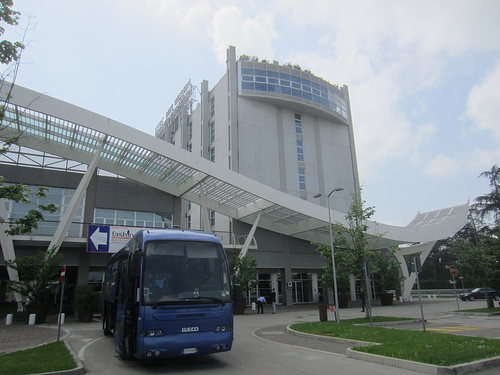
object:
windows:
[238, 67, 348, 117]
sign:
[57, 264, 69, 283]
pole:
[55, 280, 66, 344]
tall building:
[152, 45, 369, 324]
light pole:
[313, 185, 346, 324]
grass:
[289, 314, 498, 366]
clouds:
[347, 2, 498, 225]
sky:
[1, 2, 498, 226]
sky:
[76, 0, 496, 45]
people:
[257, 288, 277, 313]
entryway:
[239, 271, 271, 305]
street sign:
[432, 315, 487, 337]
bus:
[98, 226, 238, 367]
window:
[254, 72, 266, 79]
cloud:
[2, 1, 492, 234]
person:
[268, 287, 283, 315]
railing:
[5, 80, 472, 243]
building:
[2, 38, 497, 323]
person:
[256, 291, 268, 314]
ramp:
[2, 81, 485, 242]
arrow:
[88, 224, 112, 249]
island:
[274, 300, 499, 366]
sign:
[81, 219, 219, 258]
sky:
[423, 78, 472, 154]